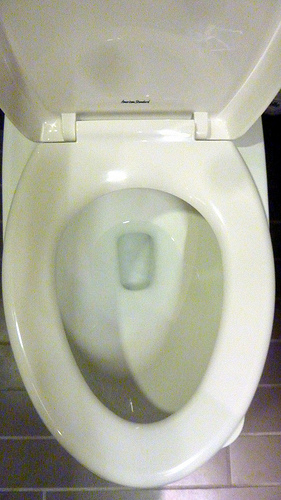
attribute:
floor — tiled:
[259, 382, 280, 500]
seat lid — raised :
[0, 2, 280, 143]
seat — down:
[1, 121, 277, 441]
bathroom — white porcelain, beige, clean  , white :
[5, 7, 276, 484]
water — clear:
[105, 221, 178, 304]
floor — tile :
[1, 111, 279, 498]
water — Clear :
[96, 212, 185, 309]